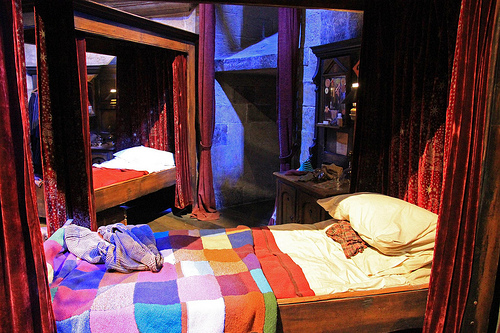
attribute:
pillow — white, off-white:
[113, 147, 177, 167]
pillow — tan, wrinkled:
[312, 189, 437, 258]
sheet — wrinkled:
[266, 218, 433, 295]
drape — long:
[189, 3, 220, 223]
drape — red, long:
[356, 1, 484, 264]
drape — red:
[117, 55, 193, 209]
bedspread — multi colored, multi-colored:
[40, 225, 275, 333]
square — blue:
[134, 303, 181, 333]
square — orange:
[223, 291, 265, 333]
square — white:
[186, 297, 226, 333]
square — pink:
[176, 274, 224, 303]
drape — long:
[268, 2, 301, 224]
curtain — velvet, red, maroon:
[33, 2, 97, 236]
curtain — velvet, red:
[0, 0, 57, 333]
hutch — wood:
[272, 43, 351, 206]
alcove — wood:
[33, 0, 209, 216]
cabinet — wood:
[87, 63, 117, 164]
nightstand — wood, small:
[274, 170, 353, 225]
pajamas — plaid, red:
[31, 174, 48, 188]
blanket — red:
[91, 166, 150, 192]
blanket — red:
[252, 225, 315, 302]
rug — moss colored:
[127, 207, 202, 238]